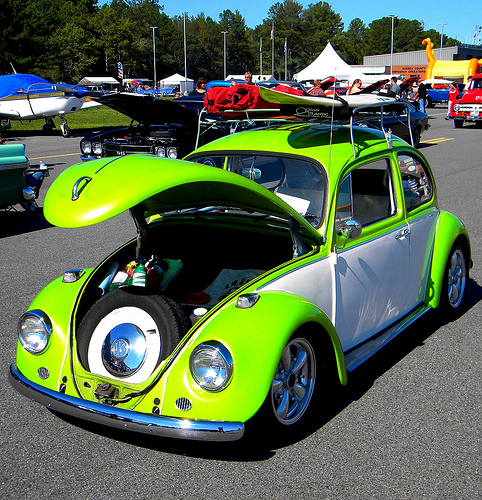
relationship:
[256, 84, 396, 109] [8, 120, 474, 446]
surfboard top of vehicle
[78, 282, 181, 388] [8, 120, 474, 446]
wheel for vehicle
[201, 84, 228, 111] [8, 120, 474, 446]
bag top of vehicle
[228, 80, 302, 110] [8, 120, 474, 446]
bag top of vehicle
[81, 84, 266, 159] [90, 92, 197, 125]
car has hood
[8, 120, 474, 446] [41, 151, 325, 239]
vehicle has hood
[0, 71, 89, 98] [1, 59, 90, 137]
tarp covers plane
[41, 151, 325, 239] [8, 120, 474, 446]
hood on vehicle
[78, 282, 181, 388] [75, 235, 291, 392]
wheel in trunk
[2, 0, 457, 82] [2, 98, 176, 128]
trees edge field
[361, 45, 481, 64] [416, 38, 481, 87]
building behind house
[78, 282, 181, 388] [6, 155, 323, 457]
wheel in front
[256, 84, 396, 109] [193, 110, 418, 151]
surfboard on rack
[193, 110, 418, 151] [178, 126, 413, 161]
rack on roof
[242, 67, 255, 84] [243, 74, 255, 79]
man wearing sunglasses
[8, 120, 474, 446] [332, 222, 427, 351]
vehicle has door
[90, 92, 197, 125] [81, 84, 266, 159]
hood of car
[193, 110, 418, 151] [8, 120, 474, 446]
rack top of vehicle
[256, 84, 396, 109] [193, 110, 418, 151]
surfboard attached to rack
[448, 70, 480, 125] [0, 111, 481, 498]
truck in lot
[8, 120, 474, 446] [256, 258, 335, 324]
vehicle has panel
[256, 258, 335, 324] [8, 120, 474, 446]
panel side of vehicle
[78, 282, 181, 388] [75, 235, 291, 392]
wheel inside trunk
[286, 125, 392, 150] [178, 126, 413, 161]
shadow on roof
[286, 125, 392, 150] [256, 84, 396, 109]
shadow of surfboard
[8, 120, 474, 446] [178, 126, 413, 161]
vehicle has roof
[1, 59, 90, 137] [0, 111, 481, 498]
plane in lot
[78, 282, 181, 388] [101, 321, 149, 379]
wheel has hubcap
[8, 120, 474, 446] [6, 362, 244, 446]
vehicle has bumper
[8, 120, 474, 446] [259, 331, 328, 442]
vehicle has tire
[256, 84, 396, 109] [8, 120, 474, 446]
surfboard on vehicle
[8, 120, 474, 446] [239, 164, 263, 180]
vehicle has mirror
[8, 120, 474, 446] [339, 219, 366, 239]
vehicle has mirror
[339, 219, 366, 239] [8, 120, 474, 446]
mirror side of vehicle